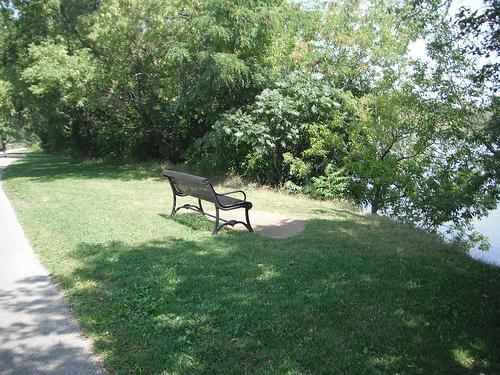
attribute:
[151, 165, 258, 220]
chair — steel, black, metal, gray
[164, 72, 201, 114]
trees — green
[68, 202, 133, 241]
grass — green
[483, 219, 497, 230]
water — blue, calm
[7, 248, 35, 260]
sidewalk — gray, concrete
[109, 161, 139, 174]
shadow — dark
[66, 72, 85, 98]
tree — green